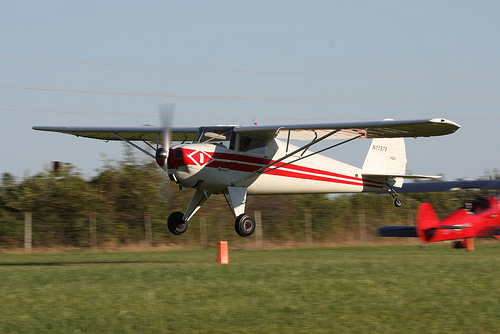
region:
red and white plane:
[48, 107, 410, 198]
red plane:
[402, 186, 487, 250]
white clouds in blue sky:
[22, 14, 113, 74]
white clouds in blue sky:
[2, 41, 86, 105]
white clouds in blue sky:
[96, 7, 186, 65]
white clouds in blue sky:
[103, 64, 155, 108]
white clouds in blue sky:
[193, 11, 270, 71]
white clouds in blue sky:
[226, 57, 280, 105]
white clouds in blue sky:
[293, 29, 361, 74]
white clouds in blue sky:
[362, 39, 424, 83]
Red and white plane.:
[30, 105, 457, 203]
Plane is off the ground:
[33, 98, 467, 318]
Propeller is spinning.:
[117, 95, 218, 213]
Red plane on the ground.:
[372, 189, 497, 250]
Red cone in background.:
[207, 235, 237, 276]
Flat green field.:
[5, 246, 495, 331]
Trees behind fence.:
[5, 165, 491, 252]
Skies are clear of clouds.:
[2, 4, 489, 186]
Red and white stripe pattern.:
[153, 150, 433, 179]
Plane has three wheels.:
[158, 175, 405, 245]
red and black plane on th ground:
[378, 193, 498, 279]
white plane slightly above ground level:
[31, 102, 460, 234]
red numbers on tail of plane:
[368, 142, 389, 154]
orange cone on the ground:
[216, 237, 231, 264]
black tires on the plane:
[165, 210, 257, 238]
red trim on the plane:
[168, 145, 385, 188]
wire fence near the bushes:
[1, 206, 416, 251]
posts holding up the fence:
[21, 209, 100, 249]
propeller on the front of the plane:
[153, 100, 180, 203]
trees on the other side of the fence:
[3, 155, 499, 244]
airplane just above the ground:
[32, 70, 459, 260]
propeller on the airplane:
[142, 88, 198, 197]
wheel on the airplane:
[224, 202, 267, 242]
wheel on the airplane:
[165, 204, 194, 246]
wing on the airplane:
[242, 95, 471, 152]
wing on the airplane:
[22, 99, 169, 167]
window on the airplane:
[195, 118, 231, 161]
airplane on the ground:
[406, 188, 498, 260]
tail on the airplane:
[413, 199, 447, 249]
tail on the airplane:
[366, 106, 406, 201]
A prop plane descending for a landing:
[31, 90, 467, 240]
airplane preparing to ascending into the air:
[370, 173, 497, 268]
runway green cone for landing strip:
[171, 240, 273, 269]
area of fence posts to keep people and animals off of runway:
[17, 193, 478, 250]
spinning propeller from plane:
[138, 103, 198, 226]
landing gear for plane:
[158, 189, 288, 244]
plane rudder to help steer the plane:
[361, 106, 438, 221]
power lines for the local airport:
[30, 58, 327, 130]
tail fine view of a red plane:
[371, 204, 498, 275]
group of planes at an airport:
[32, 60, 497, 272]